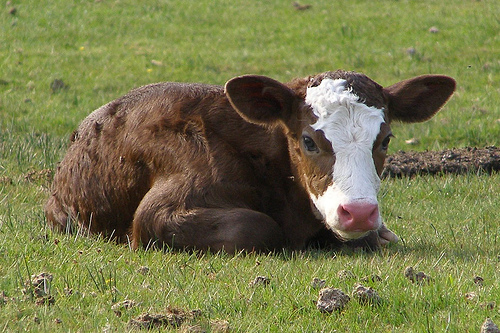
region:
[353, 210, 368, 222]
nose of a cow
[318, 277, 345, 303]
part of a stone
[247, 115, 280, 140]
edge of an ear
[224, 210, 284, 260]
part of a knee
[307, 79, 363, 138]
head of a cow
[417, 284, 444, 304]
part of a grass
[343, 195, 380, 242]
nose of a cow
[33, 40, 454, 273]
a baby brown and white cow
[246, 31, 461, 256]
a cow with a white face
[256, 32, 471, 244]
a baby cow with a pink nose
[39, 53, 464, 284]
a baby cow sitting on the ground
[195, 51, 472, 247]
a baby cow with big ears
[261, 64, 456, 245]
a cow with a white face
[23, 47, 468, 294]
a baby cow sitting in a field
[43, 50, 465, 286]
a brown and white cow sitting in a field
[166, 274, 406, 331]
clumps of dead grass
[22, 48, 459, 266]
a baby cow resting in a field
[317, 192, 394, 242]
Pink nose on cow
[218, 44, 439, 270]
brown cow with white face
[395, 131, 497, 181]
log behind cow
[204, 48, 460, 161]
brown cow with big ears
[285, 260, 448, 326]
rocks in the grass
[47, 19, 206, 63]
grass fields behind cow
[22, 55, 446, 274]
brown cow laying in grass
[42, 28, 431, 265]
baby cow in gress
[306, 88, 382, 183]
white patch on cow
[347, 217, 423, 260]
baby cow foot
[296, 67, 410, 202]
white and brown head of animal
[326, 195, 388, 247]
pink nose of the animal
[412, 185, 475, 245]
green grass next to animal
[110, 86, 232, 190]
brown body of animal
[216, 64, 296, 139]
ear of the animal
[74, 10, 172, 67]
grass behind the animal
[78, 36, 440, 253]
animal laying in gras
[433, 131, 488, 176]
brown dirt next to animal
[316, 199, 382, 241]
nostrils of the animal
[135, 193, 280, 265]
leg of the animal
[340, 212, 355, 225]
nose of a cow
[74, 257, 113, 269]
part of a grass plantation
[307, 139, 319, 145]
eye of a cow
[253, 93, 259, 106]
ear of a cow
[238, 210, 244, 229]
front leg of a cow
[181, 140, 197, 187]
body of a cow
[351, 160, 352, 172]
white part on a cow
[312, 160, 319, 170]
edge of a cow